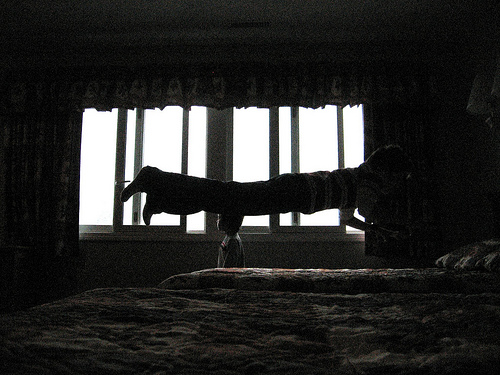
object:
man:
[118, 143, 419, 242]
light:
[78, 107, 117, 232]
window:
[79, 104, 366, 235]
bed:
[0, 287, 500, 375]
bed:
[155, 267, 500, 295]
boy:
[214, 213, 247, 268]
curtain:
[0, 109, 83, 312]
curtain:
[363, 100, 442, 260]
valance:
[0, 70, 451, 116]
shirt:
[299, 162, 389, 223]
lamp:
[464, 70, 499, 129]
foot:
[119, 165, 148, 205]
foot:
[140, 194, 154, 228]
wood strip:
[268, 106, 279, 179]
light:
[298, 104, 338, 173]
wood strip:
[180, 108, 189, 174]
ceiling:
[0, 1, 500, 47]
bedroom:
[0, 0, 500, 375]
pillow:
[434, 237, 500, 273]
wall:
[76, 241, 219, 294]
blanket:
[0, 287, 500, 375]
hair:
[363, 143, 414, 171]